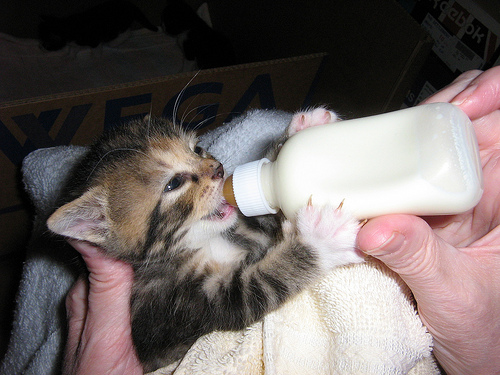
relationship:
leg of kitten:
[209, 247, 320, 327] [42, 72, 371, 374]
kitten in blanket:
[42, 110, 360, 371] [169, 256, 442, 374]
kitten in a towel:
[42, 110, 360, 371] [162, 267, 435, 371]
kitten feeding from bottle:
[42, 72, 371, 374] [223, 94, 487, 227]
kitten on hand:
[42, 72, 371, 374] [62, 250, 146, 372]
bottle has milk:
[223, 94, 487, 227] [295, 125, 405, 204]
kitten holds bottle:
[42, 72, 371, 374] [223, 94, 487, 227]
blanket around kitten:
[142, 216, 441, 373] [42, 72, 371, 374]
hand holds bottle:
[351, 63, 499, 373] [219, 99, 487, 236]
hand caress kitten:
[58, 231, 145, 373] [42, 72, 371, 374]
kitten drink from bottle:
[42, 72, 371, 374] [223, 94, 487, 227]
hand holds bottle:
[351, 63, 499, 373] [223, 94, 487, 227]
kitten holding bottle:
[42, 72, 371, 374] [200, 75, 482, 250]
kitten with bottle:
[42, 110, 360, 371] [210, 101, 482, 225]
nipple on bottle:
[221, 171, 238, 211] [162, 156, 426, 241]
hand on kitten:
[62, 235, 145, 373] [71, 144, 367, 352]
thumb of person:
[349, 216, 469, 317] [328, 58, 498, 368]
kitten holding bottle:
[42, 72, 371, 374] [219, 99, 487, 236]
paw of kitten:
[272, 191, 382, 274] [42, 72, 371, 374]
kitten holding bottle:
[42, 110, 360, 371] [223, 94, 487, 227]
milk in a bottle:
[264, 101, 468, 223] [223, 94, 487, 227]